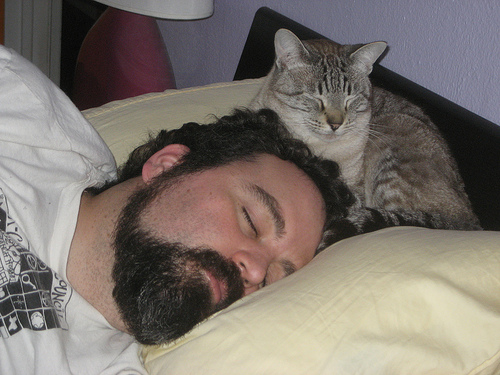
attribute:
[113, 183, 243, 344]
beard — brown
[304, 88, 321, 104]
eye — closed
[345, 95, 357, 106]
eye — closed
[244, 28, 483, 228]
cat — sleeping, grey, striped, gray, black,  sleeping in bed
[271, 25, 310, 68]
ear — gray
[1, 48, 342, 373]
man — sleeping, caucasian, lying down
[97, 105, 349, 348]
head — man's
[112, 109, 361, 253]
hair — black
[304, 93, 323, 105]
eye — closed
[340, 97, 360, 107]
eye — closed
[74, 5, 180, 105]
lamp — red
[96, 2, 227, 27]
shade — white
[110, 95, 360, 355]
head — man's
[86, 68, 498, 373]
pillow — large, white, bed, off white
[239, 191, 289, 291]
eyes — closed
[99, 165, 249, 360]
beard — brown, gray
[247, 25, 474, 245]
cat — asleep, gray tabby,  sleeping peacefully , lying down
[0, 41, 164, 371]
shirt — white, black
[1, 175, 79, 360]
writing — black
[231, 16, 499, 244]
headboard — dark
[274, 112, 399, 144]
whiskers — white, cats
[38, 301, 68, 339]
square — black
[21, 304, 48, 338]
square — black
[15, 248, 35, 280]
square — black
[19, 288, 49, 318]
square — black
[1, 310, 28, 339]
square — black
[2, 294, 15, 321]
square — black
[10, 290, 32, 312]
square — black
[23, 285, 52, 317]
square — black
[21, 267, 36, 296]
square — black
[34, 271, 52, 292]
square — black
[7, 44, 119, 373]
shirt — white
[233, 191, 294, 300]
eyes — man, his, closed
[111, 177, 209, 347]
beard — shaggy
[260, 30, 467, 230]
cat — gray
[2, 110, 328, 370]
man — caucasian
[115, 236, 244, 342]
beard — black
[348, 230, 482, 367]
pillow — beige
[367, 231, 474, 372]
pillow — beige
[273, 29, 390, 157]
cat — grey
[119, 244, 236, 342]
beard — black, thick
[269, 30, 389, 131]
cat — white, grey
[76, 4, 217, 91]
lamp — red, white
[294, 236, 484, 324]
pillow —  large ,  black headboard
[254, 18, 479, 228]
cat —   sleeping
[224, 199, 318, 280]
eyes — closed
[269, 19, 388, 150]
head — man's 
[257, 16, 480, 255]
cat — sleeping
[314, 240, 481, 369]
pillow —  light yellow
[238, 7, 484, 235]
headboard — dark brown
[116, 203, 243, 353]
facial hair — thick, black and gray